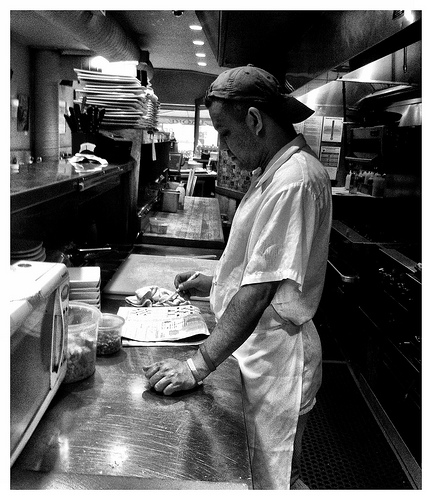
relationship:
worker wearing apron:
[145, 60, 334, 499] [218, 181, 298, 488]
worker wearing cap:
[145, 60, 334, 499] [211, 61, 313, 124]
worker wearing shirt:
[145, 60, 334, 499] [225, 151, 322, 326]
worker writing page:
[145, 60, 334, 499] [119, 303, 207, 346]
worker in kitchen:
[145, 60, 334, 499] [11, 10, 423, 491]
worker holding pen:
[145, 60, 334, 499] [170, 271, 200, 293]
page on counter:
[119, 303, 207, 346] [11, 184, 254, 488]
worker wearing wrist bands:
[145, 60, 334, 499] [185, 344, 216, 386]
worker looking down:
[145, 60, 334, 499] [7, 247, 423, 496]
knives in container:
[64, 99, 103, 136] [69, 131, 132, 162]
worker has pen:
[145, 60, 334, 499] [170, 271, 200, 293]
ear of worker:
[245, 106, 264, 137] [145, 60, 334, 499]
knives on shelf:
[64, 99, 103, 136] [9, 151, 138, 199]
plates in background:
[74, 67, 158, 131] [10, 10, 429, 196]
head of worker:
[205, 67, 300, 170] [145, 60, 334, 499]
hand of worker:
[144, 357, 197, 394] [145, 60, 334, 499]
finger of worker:
[147, 367, 163, 388] [145, 60, 334, 499]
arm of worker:
[187, 191, 312, 380] [145, 60, 334, 499]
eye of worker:
[218, 127, 231, 138] [145, 60, 334, 499]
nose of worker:
[217, 136, 229, 153] [145, 60, 334, 499]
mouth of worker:
[229, 151, 240, 167] [145, 60, 334, 499]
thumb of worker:
[178, 279, 199, 292] [145, 60, 334, 499]